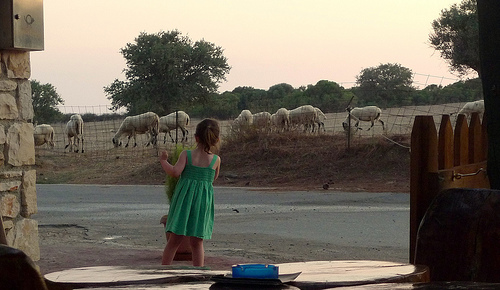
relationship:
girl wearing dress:
[157, 115, 224, 267] [164, 150, 217, 245]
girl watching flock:
[157, 115, 224, 267] [33, 100, 484, 153]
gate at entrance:
[400, 114, 491, 263] [46, 2, 485, 261]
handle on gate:
[451, 167, 489, 180] [400, 114, 491, 263]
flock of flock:
[33, 100, 484, 153] [33, 100, 484, 153]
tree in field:
[107, 22, 233, 127] [30, 100, 484, 144]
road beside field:
[33, 183, 416, 252] [30, 100, 484, 144]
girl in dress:
[157, 115, 224, 267] [164, 150, 217, 245]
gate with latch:
[400, 114, 491, 263] [451, 167, 489, 180]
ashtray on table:
[228, 258, 283, 279] [42, 259, 434, 286]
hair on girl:
[198, 117, 221, 153] [157, 115, 224, 267]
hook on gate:
[451, 167, 489, 180] [400, 114, 491, 263]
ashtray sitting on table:
[228, 258, 283, 279] [42, 259, 434, 286]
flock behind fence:
[33, 100, 484, 153] [32, 100, 499, 156]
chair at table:
[409, 184, 499, 288] [42, 259, 434, 286]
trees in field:
[187, 79, 356, 115] [30, 100, 484, 144]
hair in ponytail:
[198, 117, 221, 153] [204, 126, 217, 155]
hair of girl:
[198, 117, 221, 153] [157, 115, 224, 267]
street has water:
[33, 183, 416, 252] [95, 230, 128, 245]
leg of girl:
[187, 235, 207, 268] [157, 115, 224, 267]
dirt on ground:
[42, 224, 90, 249] [33, 183, 416, 252]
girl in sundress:
[157, 115, 224, 267] [164, 150, 217, 245]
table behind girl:
[42, 259, 434, 286] [157, 115, 224, 267]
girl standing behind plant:
[157, 115, 224, 267] [159, 148, 184, 209]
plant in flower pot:
[159, 148, 184, 209] [158, 216, 198, 264]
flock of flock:
[32, 99, 419, 163] [33, 100, 484, 153]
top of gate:
[409, 112, 492, 120] [400, 114, 491, 263]